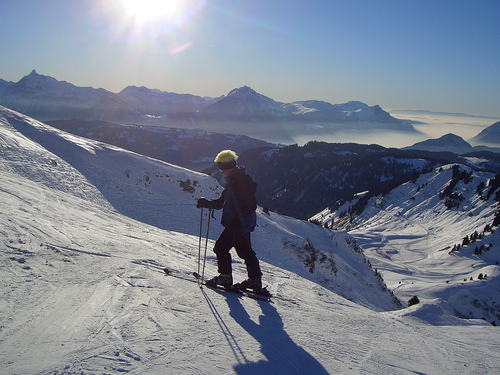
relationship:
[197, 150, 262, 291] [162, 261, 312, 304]
man has snowboard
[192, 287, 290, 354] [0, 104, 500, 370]
shadow on snow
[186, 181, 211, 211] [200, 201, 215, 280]
hands gripping gripping ski pole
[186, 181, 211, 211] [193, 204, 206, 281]
hands gripping gripping ski pole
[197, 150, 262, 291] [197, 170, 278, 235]
man wearing blue jacket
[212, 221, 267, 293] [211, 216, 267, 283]
man wearing black pants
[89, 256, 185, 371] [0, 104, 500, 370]
ski tracks in snow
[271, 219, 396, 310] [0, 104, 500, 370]
black rocks in snow